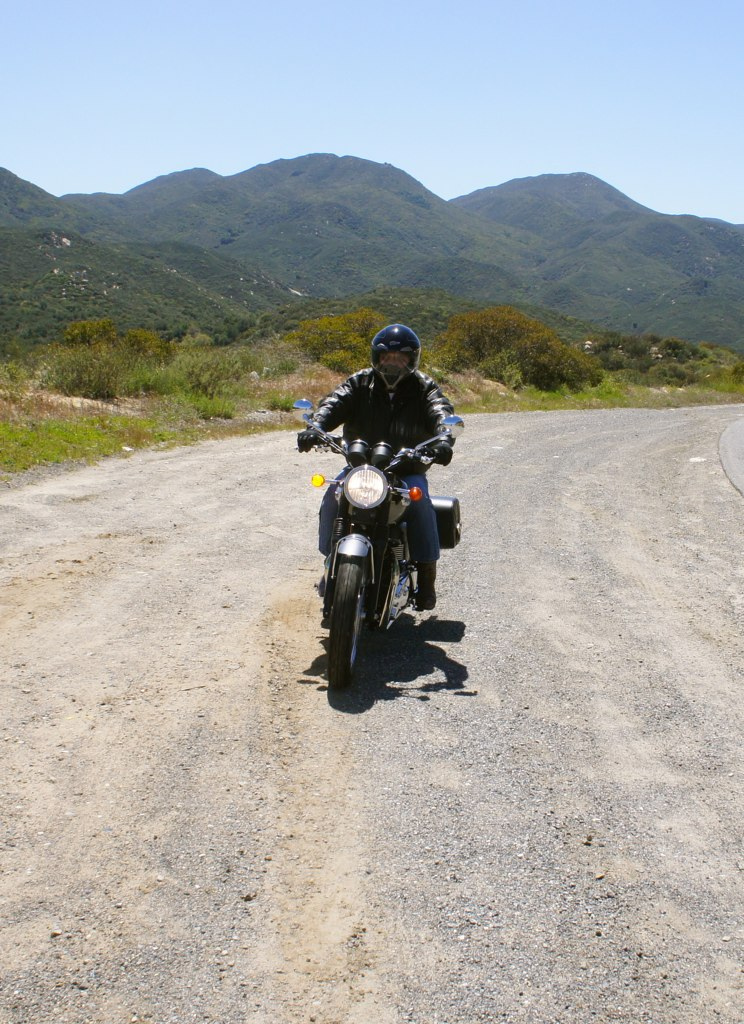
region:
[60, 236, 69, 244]
A piece of bare rock in the mountain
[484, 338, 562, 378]
A thick bush on the side of the road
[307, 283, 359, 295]
A valley between two mountains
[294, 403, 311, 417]
The metallic side mirror reflecting light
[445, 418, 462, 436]
The metallic surface of a motorbike side mirror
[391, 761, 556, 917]
A road covered with loose gravel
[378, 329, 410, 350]
A rider wearing a safety helmet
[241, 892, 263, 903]
rock on the ground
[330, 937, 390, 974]
rock on the ground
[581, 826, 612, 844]
rock on the ground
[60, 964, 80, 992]
rock on the ground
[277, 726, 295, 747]
rock on the ground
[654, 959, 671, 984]
rock on the ground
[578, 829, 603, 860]
rock on the ground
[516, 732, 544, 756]
rock on the ground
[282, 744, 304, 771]
rock on the ground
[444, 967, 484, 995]
rock on the ground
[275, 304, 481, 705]
person on a motorcycle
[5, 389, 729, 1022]
the road is paved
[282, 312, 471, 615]
man wears black clothes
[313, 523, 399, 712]
front wheel of a motorcycle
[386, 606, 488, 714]
shadow on the ground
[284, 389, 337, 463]
mirror of a motorcycle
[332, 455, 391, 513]
light on front the motorcycle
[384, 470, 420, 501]
red light on the motorcycle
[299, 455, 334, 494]
yellow light on the motorcycle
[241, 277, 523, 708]
man riding bike on dirt path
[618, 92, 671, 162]
white clouds in blue sky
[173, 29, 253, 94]
white clouds in blue sky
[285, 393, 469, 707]
The motorcycle is casting a shadow.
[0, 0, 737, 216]
The sky is blue with some haze near the mountains.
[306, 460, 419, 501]
One headlight has a smaller light on each side.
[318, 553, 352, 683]
The tire is black on a silver wheel.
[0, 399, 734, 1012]
The road is gray and is gravel.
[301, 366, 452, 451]
The jacket is black and shiny in places.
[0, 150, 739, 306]
The mountains are green and steep.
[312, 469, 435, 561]
The legs have on blue pants.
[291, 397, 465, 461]
Two mirrors are on the handlebars.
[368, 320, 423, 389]
a black motorcycle helmet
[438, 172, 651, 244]
a large mountain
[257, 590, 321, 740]
a section of dirt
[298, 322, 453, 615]
motorcyclist on top of motorcycle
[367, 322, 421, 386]
black motorcyclist helmet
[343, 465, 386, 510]
round bright front light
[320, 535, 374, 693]
round black front wheel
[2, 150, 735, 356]
large green mountain in the background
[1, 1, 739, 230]
light blue clear sky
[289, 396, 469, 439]
small gray metal motorcycle rearviews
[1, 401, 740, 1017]
large dirty road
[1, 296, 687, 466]
bushes in left side of road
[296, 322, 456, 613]
motorcyclist wearing leather jacket and blue jeans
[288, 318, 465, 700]
man sitting on a motorcycle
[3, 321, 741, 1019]
man riding on a dirt road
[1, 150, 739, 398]
mountains in the distance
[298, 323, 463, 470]
man wearing a black helmet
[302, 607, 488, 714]
shadow in the dirt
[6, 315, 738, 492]
vegetation growing alongside a road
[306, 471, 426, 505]
yellow and red lights of a motorcycle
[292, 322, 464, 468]
man in a black jacket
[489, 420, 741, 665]
tracks in the dirt